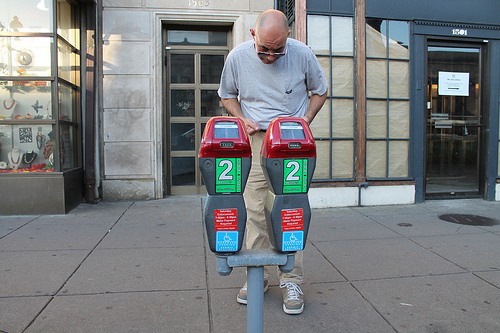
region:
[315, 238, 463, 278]
a piece of concrete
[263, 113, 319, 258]
a red and gray parking meter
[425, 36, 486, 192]
the door of a building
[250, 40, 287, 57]
a man's sunglasses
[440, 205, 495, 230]
a manhole cover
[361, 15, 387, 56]
a window of a building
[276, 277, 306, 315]
a man's tennis shoe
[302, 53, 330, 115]
the arm of a man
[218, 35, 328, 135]
a man's short sleeve shirt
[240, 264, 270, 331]
a short gray pole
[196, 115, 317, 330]
a pair of car time meters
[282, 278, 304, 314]
a single mans show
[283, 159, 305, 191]
a white number two on a green sticker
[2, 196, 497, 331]
a dirty sidewalk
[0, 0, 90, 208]
a shop window filled with necklaces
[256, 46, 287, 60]
a black pair of sunglasses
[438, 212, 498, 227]
a black manhole cover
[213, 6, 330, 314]
a man looking at a car meter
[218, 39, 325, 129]
a light grey tshirt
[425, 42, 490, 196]
a glass store door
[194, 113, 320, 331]
a double headed parking meter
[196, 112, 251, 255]
a red and grey parking meter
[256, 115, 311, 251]
a red and grey parking meter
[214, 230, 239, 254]
a blue handicapped sticker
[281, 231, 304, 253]
a blue handicapped sticker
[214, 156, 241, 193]
green sticker number 2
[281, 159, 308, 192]
green sticker number 2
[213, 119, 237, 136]
a digital meter display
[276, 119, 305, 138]
a digital meter display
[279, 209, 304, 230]
a square red sticker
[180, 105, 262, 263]
red meter with number two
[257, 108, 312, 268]
red meter with red label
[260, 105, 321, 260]
parking meter with handicap sticker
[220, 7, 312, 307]
man wearing gray shirt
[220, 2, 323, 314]
man wearing tan pants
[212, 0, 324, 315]
man wearing sunglasses with silver frame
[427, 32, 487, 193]
glass door with white sign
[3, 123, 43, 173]
necklaces in display window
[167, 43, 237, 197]
door with glass panels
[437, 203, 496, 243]
man hole on sidewalk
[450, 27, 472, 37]
gold numbers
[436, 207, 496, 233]
a brown manhole cover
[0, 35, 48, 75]
the window of a building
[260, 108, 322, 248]
a colorful parking meter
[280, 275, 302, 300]
white shoe strings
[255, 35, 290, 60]
a man's dark sunglasses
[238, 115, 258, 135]
the hand of a man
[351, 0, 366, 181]
a tall wooden pole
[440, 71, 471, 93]
a small white sign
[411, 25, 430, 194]
a tall black door trim